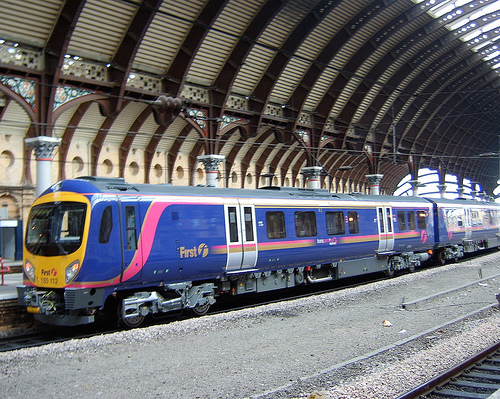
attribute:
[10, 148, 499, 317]
train — blue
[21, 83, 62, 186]
column — white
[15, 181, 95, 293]
front — yellow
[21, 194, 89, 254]
windshield — large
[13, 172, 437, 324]
engine — blue, train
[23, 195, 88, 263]
windshield — train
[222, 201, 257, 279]
doors — train, double, passenger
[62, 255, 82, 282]
headlight — train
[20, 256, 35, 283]
headlight — train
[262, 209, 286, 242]
window — train, passenger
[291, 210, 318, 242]
window — passenger, train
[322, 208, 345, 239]
window — train, passenger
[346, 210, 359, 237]
window — passenger, train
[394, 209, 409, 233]
window — train, passenger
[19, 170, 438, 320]
train — blue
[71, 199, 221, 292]
stripe — pink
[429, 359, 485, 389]
track — black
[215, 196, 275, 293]
door — silver, metal, train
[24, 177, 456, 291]
train car — long, blue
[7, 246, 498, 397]
tracks — train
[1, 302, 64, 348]
gravel — some